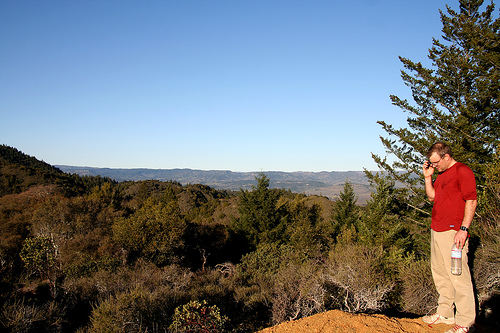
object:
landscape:
[31, 108, 394, 217]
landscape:
[2, 142, 498, 327]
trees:
[18, 228, 90, 321]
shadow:
[182, 221, 256, 266]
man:
[421, 142, 478, 333]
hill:
[252, 309, 469, 332]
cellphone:
[425, 159, 432, 169]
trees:
[52, 202, 187, 266]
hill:
[3, 143, 423, 307]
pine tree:
[361, 0, 497, 323]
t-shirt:
[430, 162, 478, 237]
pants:
[430, 229, 476, 327]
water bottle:
[451, 244, 463, 276]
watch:
[460, 226, 470, 232]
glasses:
[429, 161, 441, 166]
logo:
[440, 178, 455, 189]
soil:
[300, 321, 368, 332]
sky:
[2, 2, 378, 119]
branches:
[199, 248, 210, 270]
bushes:
[272, 242, 400, 319]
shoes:
[421, 313, 456, 324]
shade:
[479, 320, 499, 333]